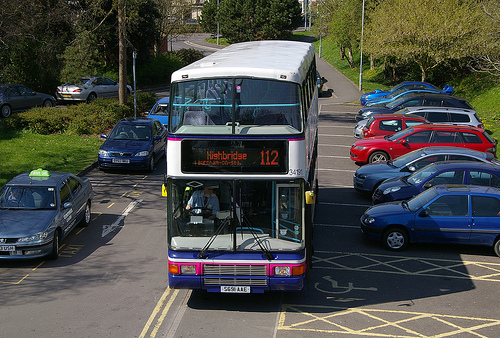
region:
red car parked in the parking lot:
[348, 122, 497, 163]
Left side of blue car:
[361, 187, 498, 254]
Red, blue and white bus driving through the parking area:
[166, 39, 320, 296]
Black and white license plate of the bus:
[218, 283, 251, 294]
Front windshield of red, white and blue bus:
[163, 176, 303, 249]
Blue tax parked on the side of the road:
[0, 166, 94, 261]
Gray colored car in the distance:
[56, 72, 118, 99]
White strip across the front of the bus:
[164, 256, 308, 263]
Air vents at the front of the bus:
[200, 263, 268, 275]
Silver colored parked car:
[354, 103, 480, 137]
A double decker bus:
[162, 34, 324, 304]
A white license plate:
[217, 279, 255, 299]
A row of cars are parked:
[345, 76, 498, 261]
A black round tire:
[381, 223, 411, 258]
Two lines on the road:
[137, 281, 179, 336]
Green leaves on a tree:
[199, 1, 305, 41]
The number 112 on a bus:
[254, 146, 283, 169]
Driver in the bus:
[178, 179, 223, 222]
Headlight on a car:
[14, 229, 46, 249]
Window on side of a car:
[421, 192, 473, 224]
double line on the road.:
[147, 310, 165, 331]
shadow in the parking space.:
[395, 281, 420, 290]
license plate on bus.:
[215, 283, 251, 297]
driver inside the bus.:
[186, 195, 223, 210]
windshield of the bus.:
[255, 195, 282, 215]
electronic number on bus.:
[258, 148, 281, 166]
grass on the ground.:
[23, 145, 61, 150]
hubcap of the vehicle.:
[386, 233, 403, 253]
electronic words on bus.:
[195, 150, 248, 170]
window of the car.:
[437, 200, 463, 208]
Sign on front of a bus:
[177, 140, 294, 173]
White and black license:
[216, 283, 257, 299]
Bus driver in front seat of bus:
[179, 177, 229, 238]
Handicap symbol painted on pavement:
[312, 260, 386, 320]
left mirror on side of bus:
[300, 185, 322, 210]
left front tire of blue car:
[377, 216, 414, 261]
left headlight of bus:
[269, 262, 298, 279]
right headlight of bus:
[171, 259, 203, 282]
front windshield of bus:
[161, 174, 304, 258]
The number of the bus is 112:
[253, 143, 292, 176]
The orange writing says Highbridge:
[197, 145, 258, 162]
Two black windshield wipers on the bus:
[205, 206, 275, 256]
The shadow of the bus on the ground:
[308, 183, 483, 330]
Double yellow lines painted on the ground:
[147, 288, 190, 332]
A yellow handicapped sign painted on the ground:
[314, 273, 385, 310]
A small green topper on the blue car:
[27, 165, 56, 182]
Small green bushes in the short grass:
[17, 97, 122, 129]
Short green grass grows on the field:
[10, 137, 75, 170]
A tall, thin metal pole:
[345, 0, 372, 85]